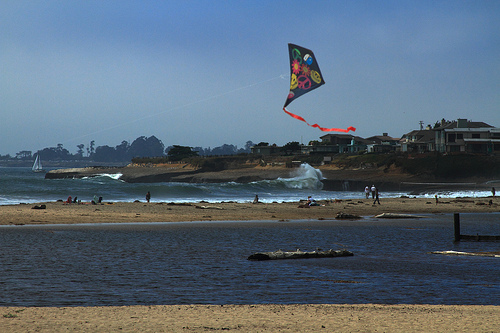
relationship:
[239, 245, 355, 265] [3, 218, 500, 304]
log floating on water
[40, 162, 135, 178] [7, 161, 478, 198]
pier in water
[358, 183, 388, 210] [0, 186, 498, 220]
people along shoreline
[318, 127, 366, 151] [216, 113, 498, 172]
house on hillside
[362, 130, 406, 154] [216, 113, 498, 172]
house on hillside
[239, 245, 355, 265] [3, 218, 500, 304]
log in water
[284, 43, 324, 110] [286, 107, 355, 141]
kite has ribbon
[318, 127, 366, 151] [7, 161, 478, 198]
house near water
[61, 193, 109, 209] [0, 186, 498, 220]
people on shoreline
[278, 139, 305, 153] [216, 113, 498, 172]
tree in hillside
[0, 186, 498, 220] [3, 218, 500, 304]
shoreline meets water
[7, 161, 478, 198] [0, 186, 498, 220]
water breaking on shoreline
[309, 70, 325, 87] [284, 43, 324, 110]
smiley face on kite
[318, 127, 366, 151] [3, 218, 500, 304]
house near water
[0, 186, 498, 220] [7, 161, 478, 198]
shoreline between water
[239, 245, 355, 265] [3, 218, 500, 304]
log on water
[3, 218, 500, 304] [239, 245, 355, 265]
water has log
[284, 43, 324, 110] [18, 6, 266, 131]
kite in air